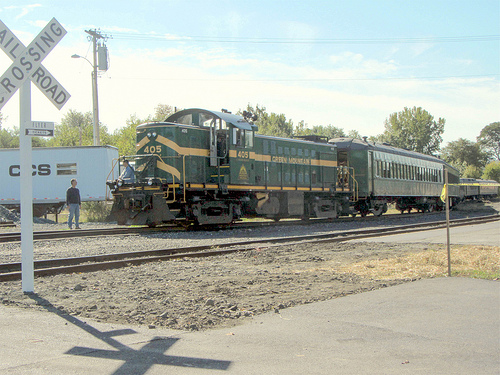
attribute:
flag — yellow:
[442, 183, 452, 203]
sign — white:
[0, 15, 72, 110]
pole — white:
[11, 82, 45, 357]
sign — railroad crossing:
[1, 17, 82, 129]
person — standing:
[54, 175, 101, 235]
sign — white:
[1, 12, 70, 114]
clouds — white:
[204, 52, 260, 74]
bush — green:
[370, 100, 457, 166]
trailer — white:
[9, 128, 134, 215]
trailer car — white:
[1, 145, 121, 224]